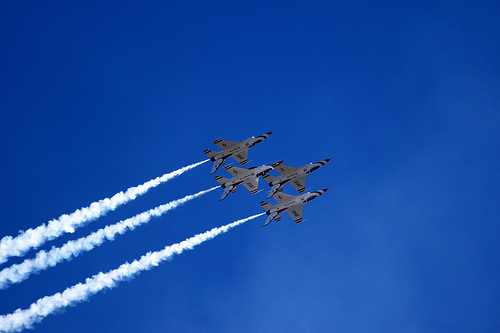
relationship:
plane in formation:
[202, 126, 282, 163] [190, 111, 340, 243]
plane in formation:
[216, 161, 285, 195] [190, 111, 340, 243]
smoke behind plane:
[112, 164, 142, 203] [202, 126, 282, 163]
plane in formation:
[258, 189, 337, 229] [190, 111, 340, 243]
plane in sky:
[202, 126, 282, 163] [199, 31, 241, 60]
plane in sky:
[216, 161, 285, 195] [199, 31, 241, 60]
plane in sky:
[258, 189, 337, 229] [199, 31, 241, 60]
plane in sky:
[272, 154, 337, 185] [199, 31, 241, 60]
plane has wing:
[202, 126, 282, 163] [216, 135, 222, 145]